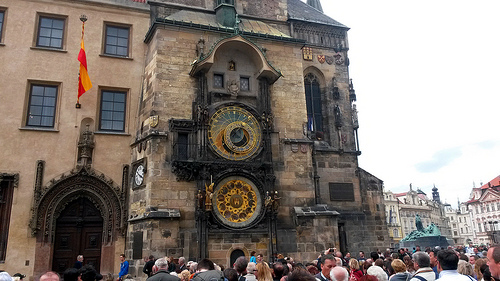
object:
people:
[405, 250, 438, 281]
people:
[313, 255, 340, 280]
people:
[251, 261, 277, 281]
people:
[329, 266, 351, 280]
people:
[151, 252, 185, 280]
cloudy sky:
[299, 0, 500, 207]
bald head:
[329, 266, 347, 281]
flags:
[70, 43, 95, 98]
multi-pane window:
[99, 18, 131, 62]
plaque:
[329, 179, 356, 203]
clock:
[128, 160, 149, 186]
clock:
[199, 102, 270, 169]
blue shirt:
[116, 254, 131, 277]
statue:
[400, 212, 451, 252]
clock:
[193, 168, 280, 230]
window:
[34, 10, 68, 50]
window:
[98, 83, 126, 136]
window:
[22, 76, 59, 131]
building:
[381, 177, 498, 256]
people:
[482, 244, 500, 281]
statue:
[76, 116, 101, 172]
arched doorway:
[26, 158, 133, 281]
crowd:
[1, 242, 498, 281]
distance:
[385, 186, 496, 224]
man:
[115, 250, 135, 277]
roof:
[476, 175, 500, 189]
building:
[0, 0, 389, 281]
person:
[390, 258, 413, 280]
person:
[405, 250, 438, 280]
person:
[233, 255, 249, 278]